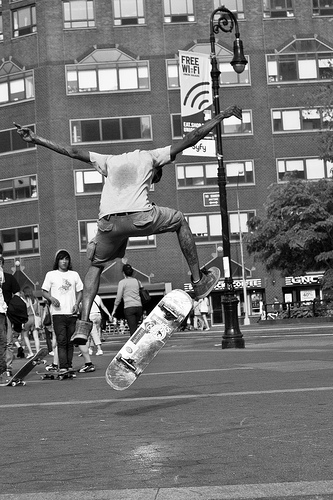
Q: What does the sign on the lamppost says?
A: Free Wi-Fi.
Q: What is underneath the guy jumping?
A: A skateboard.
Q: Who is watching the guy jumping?
A: The guy with the white shirt.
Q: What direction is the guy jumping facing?
A: Away from us.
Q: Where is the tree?
A: On the right.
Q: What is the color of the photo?
A: Black and white.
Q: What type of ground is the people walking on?
A: Concrete.